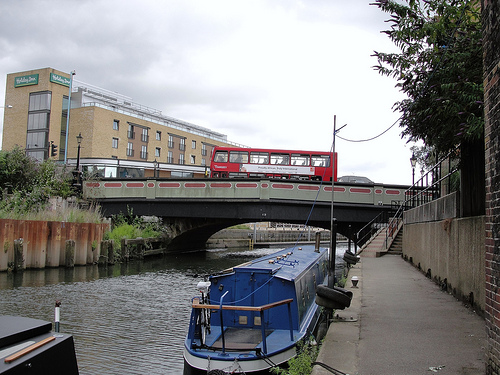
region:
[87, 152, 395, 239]
A bridge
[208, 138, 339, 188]
A red double-decker bus on the bridge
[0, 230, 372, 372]
A small river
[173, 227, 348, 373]
A blue boat on the river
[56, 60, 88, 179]
A street light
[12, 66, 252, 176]
A large holiday inn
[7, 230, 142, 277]
Some wooden pylons in the water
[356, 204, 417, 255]
a set of stairs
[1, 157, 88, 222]
some bushes next to the bridge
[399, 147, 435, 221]
a street light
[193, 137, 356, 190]
Red bus going over a bride.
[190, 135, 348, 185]
The bus is red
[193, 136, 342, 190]
The bus is a double decker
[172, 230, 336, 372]
Blue boat in the water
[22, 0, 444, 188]
The sky is gray and cloudy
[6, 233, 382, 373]
A canal between streets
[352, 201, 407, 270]
Staircase leading to the canal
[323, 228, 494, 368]
Concrete sidewalk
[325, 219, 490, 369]
Nobody on the sidewalk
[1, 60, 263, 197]
Holiday Inn hotel overlooking the canal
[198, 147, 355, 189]
large red bus going over short bridge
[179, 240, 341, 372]
blue ferry boat tied to cement dock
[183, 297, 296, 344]
railing on ferry boat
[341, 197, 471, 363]
cement dock with stairs leading up to bridge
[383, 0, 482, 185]
green tree hanging over the right side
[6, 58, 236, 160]
tan building in the distance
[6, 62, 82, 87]
tan building is a Holiday Inn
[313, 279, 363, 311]
old tires used as bumpers to protect the boat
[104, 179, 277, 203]
red shapes painted on bridge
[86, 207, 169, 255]
bushes and grasses are overgrown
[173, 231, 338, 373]
blue boat in the water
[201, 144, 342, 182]
red bus on a bridge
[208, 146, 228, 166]
window on a bus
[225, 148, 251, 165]
window on a bus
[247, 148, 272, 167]
window on a bus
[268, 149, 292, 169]
window on a bus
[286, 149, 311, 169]
window on a bus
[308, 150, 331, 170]
window on a bus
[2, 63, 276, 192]
large building made of brick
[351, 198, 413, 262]
concrete staircase near the water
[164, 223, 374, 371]
long blue boat on a river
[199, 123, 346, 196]
red and white bus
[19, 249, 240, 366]
ripply water of a river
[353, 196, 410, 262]
stairs with railings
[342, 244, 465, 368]
cement walkway along river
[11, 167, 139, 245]
grassy weeds and bushes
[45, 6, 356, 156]
grey cloudy sky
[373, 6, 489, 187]
tree full with green leaves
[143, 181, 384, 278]
arched bridge over the river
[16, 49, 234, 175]
brick building with many windows